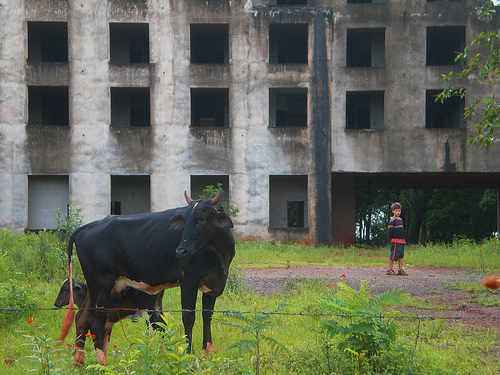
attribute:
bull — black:
[70, 208, 234, 354]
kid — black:
[379, 185, 408, 274]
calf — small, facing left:
[66, 283, 148, 326]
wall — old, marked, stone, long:
[155, 8, 187, 87]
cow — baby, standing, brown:
[61, 195, 239, 284]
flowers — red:
[11, 303, 45, 353]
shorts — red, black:
[390, 249, 403, 257]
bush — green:
[247, 305, 281, 344]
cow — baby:
[44, 273, 177, 365]